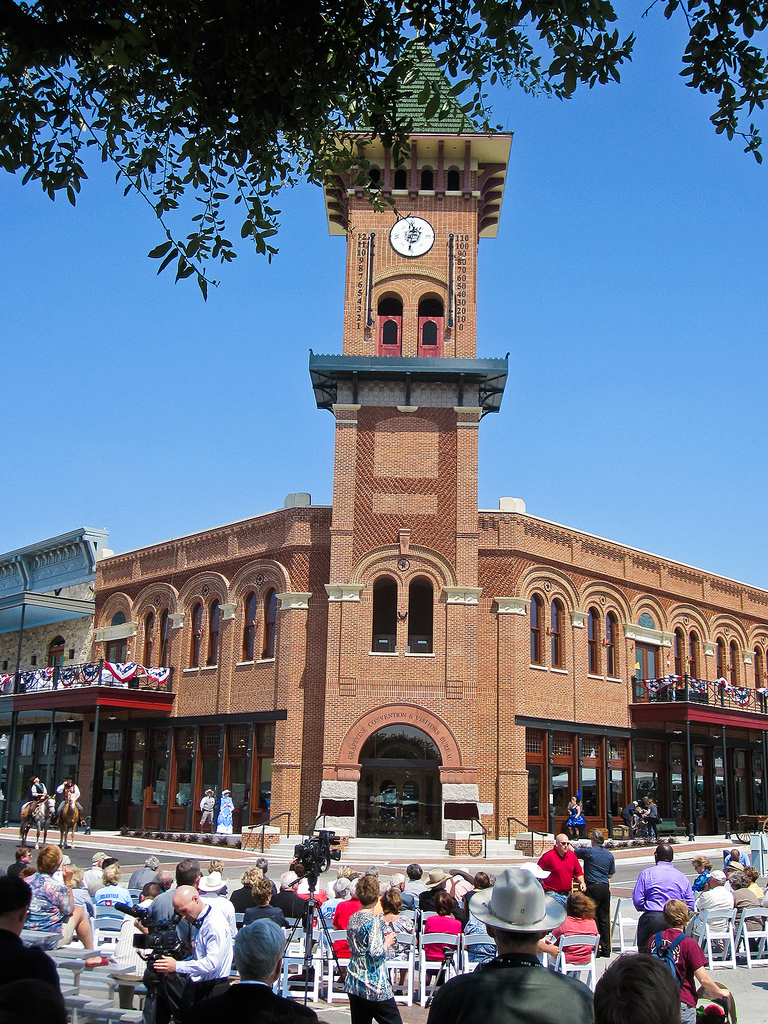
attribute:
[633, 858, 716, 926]
shirt — purple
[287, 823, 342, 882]
camera — video 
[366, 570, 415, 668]
building — side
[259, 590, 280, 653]
window — side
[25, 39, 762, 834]
brick building — brick , side 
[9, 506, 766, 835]
building — side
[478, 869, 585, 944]
brimmed hat — brimmed 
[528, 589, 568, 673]
window — side 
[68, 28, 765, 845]
building — side, brick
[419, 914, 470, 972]
shirt — pink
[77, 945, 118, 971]
shoes — red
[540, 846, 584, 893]
shirt — red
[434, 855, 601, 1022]
man — back 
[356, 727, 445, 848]
doorway — arched glass 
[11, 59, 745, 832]
building — side